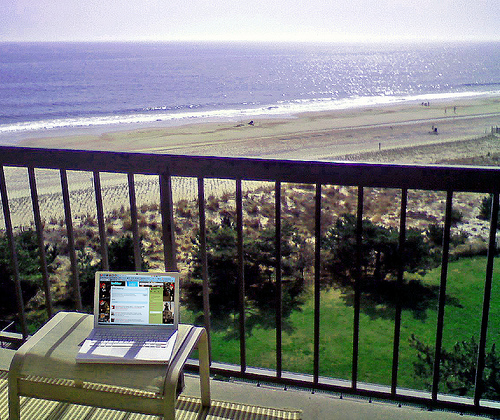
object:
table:
[9, 310, 210, 420]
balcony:
[0, 145, 499, 418]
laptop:
[75, 269, 180, 363]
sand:
[0, 92, 500, 228]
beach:
[0, 89, 499, 234]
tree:
[322, 212, 374, 290]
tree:
[387, 227, 442, 281]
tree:
[180, 218, 258, 321]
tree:
[0, 230, 59, 318]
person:
[444, 106, 447, 114]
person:
[453, 105, 456, 115]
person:
[433, 122, 438, 133]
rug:
[0, 367, 302, 420]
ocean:
[0, 39, 499, 132]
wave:
[7, 110, 154, 123]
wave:
[261, 94, 398, 116]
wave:
[408, 84, 488, 100]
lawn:
[171, 249, 499, 400]